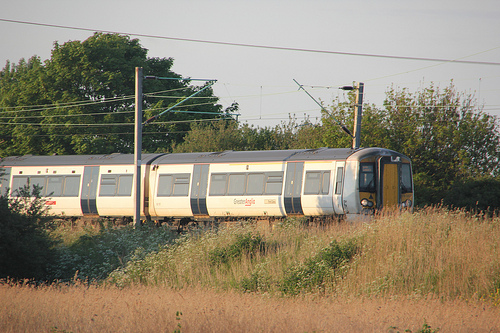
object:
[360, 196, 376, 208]
lights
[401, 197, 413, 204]
lights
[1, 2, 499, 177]
sky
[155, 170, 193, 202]
window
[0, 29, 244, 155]
trees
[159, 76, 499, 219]
trees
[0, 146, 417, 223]
train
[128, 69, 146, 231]
post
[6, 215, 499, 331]
grassy field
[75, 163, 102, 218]
door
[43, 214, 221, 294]
flowers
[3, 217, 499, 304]
hill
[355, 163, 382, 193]
windows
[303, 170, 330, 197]
window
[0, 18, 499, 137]
power lines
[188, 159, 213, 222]
door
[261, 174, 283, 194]
window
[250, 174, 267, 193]
window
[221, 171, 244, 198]
window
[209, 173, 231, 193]
window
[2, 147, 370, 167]
top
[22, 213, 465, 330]
weeds